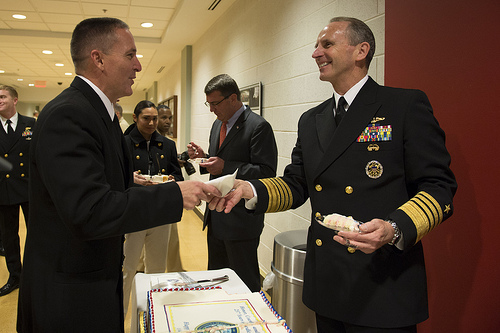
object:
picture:
[239, 81, 262, 110]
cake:
[163, 298, 273, 332]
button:
[315, 211, 321, 219]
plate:
[313, 214, 364, 232]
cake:
[133, 267, 253, 330]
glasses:
[204, 93, 233, 108]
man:
[187, 74, 279, 292]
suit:
[204, 105, 278, 293]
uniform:
[246, 75, 458, 331]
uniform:
[0, 114, 38, 274]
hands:
[175, 179, 222, 210]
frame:
[238, 81, 263, 117]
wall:
[191, 0, 385, 278]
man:
[13, 16, 223, 332]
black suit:
[15, 76, 184, 332]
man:
[207, 16, 458, 332]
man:
[136, 104, 186, 273]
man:
[0, 84, 38, 297]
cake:
[318, 212, 362, 233]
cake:
[150, 173, 175, 184]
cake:
[145, 287, 291, 332]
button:
[346, 245, 355, 253]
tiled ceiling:
[0, 0, 178, 92]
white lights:
[11, 14, 28, 21]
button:
[344, 186, 354, 194]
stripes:
[258, 176, 293, 213]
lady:
[122, 99, 184, 332]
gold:
[397, 190, 443, 245]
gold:
[258, 176, 292, 213]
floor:
[1, 205, 208, 331]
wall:
[383, 1, 498, 332]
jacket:
[122, 126, 184, 187]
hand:
[333, 217, 395, 253]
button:
[315, 184, 322, 191]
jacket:
[246, 75, 458, 328]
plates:
[187, 156, 212, 164]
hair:
[329, 16, 377, 70]